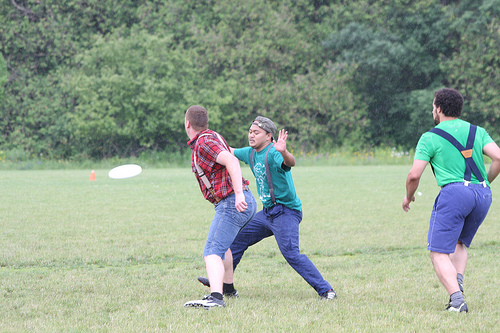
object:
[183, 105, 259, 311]
man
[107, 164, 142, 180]
disc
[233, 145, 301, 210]
shirt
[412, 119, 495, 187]
shirt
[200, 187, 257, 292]
legs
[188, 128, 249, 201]
plaid shirt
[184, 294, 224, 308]
shoes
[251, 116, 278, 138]
cap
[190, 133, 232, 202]
suspenders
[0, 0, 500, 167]
bush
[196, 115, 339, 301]
man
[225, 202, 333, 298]
jeans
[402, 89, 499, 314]
man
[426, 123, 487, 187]
suspenders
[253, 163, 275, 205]
design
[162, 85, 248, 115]
wall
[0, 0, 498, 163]
trees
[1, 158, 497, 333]
field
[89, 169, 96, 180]
cone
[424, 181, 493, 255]
shorts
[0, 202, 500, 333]
grass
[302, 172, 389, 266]
grass field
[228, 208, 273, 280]
leg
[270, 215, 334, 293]
leg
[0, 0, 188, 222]
air